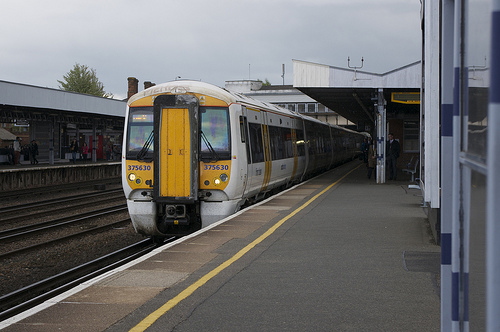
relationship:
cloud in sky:
[107, 92, 122, 103] [1, 1, 424, 111]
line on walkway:
[126, 156, 368, 326] [31, 152, 451, 331]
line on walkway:
[0, 169, 306, 329] [31, 152, 451, 331]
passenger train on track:
[120, 77, 373, 247] [2, 184, 178, 316]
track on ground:
[2, 184, 178, 316] [6, 178, 197, 313]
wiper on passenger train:
[199, 127, 222, 158] [120, 77, 373, 247]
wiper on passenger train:
[136, 126, 163, 164] [120, 77, 373, 247]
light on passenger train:
[214, 178, 222, 188] [120, 77, 373, 247]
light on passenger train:
[129, 172, 137, 182] [120, 77, 373, 247]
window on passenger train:
[199, 104, 234, 167] [120, 77, 373, 247]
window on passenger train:
[128, 108, 159, 164] [120, 77, 373, 247]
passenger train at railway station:
[120, 77, 373, 247] [3, 50, 448, 217]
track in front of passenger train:
[2, 184, 178, 316] [120, 77, 373, 247]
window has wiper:
[199, 104, 234, 167] [199, 127, 222, 158]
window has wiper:
[128, 108, 159, 164] [136, 126, 163, 164]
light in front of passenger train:
[214, 178, 222, 188] [120, 77, 373, 247]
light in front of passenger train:
[129, 172, 137, 182] [120, 77, 373, 247]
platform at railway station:
[4, 151, 127, 193] [3, 50, 448, 217]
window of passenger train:
[199, 104, 234, 167] [120, 77, 373, 247]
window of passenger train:
[128, 108, 159, 164] [120, 77, 373, 247]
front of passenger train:
[126, 88, 238, 203] [120, 77, 373, 247]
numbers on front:
[200, 162, 231, 173] [126, 88, 238, 203]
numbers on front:
[128, 164, 157, 172] [126, 88, 238, 203]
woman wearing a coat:
[364, 134, 380, 181] [366, 142, 378, 170]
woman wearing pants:
[364, 134, 380, 181] [367, 167, 378, 178]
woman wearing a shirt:
[364, 134, 380, 181] [372, 143, 376, 155]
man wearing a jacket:
[384, 130, 403, 182] [383, 138, 401, 163]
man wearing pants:
[384, 130, 403, 182] [385, 154, 397, 180]